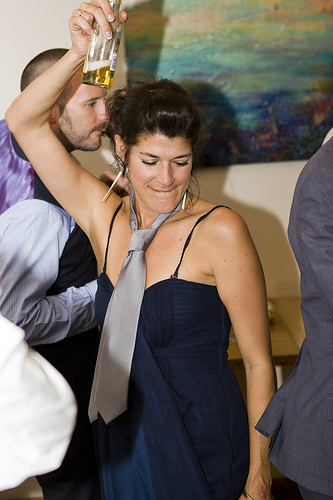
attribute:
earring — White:
[100, 165, 124, 203]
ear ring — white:
[177, 187, 187, 212]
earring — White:
[101, 171, 121, 201]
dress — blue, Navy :
[82, 202, 251, 498]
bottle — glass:
[82, 3, 133, 100]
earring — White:
[180, 193, 194, 207]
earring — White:
[100, 167, 128, 204]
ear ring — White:
[179, 189, 191, 208]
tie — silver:
[87, 209, 185, 424]